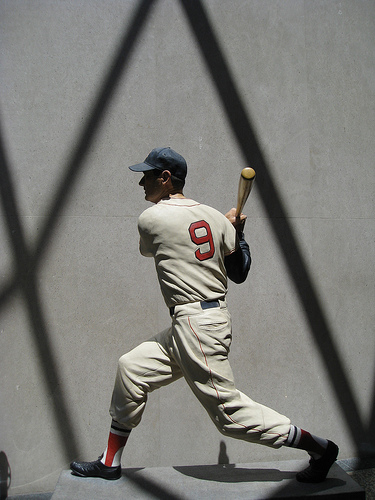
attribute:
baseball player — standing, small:
[66, 153, 339, 484]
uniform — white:
[111, 191, 300, 452]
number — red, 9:
[187, 217, 215, 263]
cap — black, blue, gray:
[129, 147, 187, 175]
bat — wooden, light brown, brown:
[235, 166, 254, 224]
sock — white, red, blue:
[99, 426, 130, 467]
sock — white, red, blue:
[285, 423, 301, 446]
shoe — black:
[299, 438, 338, 485]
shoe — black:
[68, 460, 125, 481]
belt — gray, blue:
[169, 294, 227, 316]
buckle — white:
[171, 298, 202, 317]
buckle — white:
[217, 294, 231, 308]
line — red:
[105, 428, 119, 464]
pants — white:
[110, 305, 301, 448]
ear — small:
[159, 169, 178, 192]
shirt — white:
[136, 189, 238, 306]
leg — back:
[198, 354, 341, 474]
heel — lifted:
[283, 422, 324, 457]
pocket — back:
[206, 320, 232, 356]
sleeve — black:
[217, 214, 249, 284]